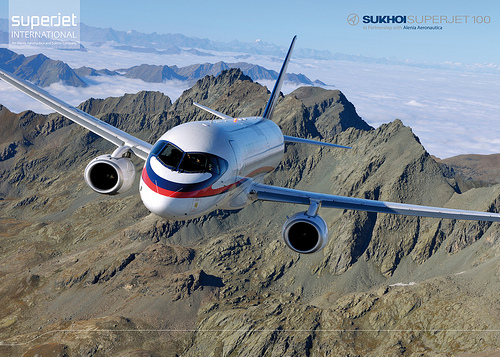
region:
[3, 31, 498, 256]
Red, white and blue airplane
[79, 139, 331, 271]
Silver engines on airplane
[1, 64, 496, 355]
Large brown mountain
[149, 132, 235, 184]
Large black window on airplane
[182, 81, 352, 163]
Two small wings on airplane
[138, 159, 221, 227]
Red white and blue nose of airplane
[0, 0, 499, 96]
Small mountains in the distance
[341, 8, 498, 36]
Blue and grey lettering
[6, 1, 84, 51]
White superjet logo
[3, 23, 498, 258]
Airplane flying over mountains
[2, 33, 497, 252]
jet airplane flying over mountainous area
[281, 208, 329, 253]
engine on left wing of the jet airplane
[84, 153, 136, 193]
engine on the right wing of the jet aircraft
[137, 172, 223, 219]
red, which and blue nose of the jet airplane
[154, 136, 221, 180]
windows of the cockpit of the jet airplane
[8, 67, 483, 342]
tall gray mountains behind the jet airplane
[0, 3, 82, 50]
advertising in white letters on the photo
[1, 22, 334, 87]
peaks of mountains showing through clouds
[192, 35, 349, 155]
blue and gray tail of a jet airplane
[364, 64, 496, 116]
gray and white clouds behind the airplane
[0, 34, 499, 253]
Airplane flying over a cliff.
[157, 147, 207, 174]
the windshield of the airplane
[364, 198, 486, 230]
the wing on the airplane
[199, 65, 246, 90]
the peak of the mountain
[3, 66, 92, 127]
a wing on the airplane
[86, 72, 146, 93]
the clouds in the sky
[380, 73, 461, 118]
the clouds are white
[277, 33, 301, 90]
the tail of the airplane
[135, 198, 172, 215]
the nose of the airplane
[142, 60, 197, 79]
the mountains are brown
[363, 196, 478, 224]
the airplane has a wing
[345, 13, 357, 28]
The small arrow logo on the left side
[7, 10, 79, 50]
The super jet logo on the left side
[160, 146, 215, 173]
The wind sheild on the plane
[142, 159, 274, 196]
The red and blue stripes on the plane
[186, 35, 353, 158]
The tail of the plane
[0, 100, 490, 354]
The mountains below the plane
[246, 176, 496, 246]
The right wing of the plane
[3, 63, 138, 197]
The left wing on the plane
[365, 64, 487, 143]
The clouds meeting the mountain peak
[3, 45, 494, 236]
An airplane